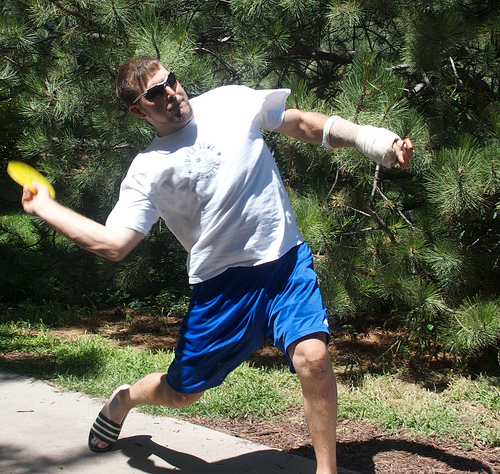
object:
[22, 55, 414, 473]
man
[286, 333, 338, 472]
bare leg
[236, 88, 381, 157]
arm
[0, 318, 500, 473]
trail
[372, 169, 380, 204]
bark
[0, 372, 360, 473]
path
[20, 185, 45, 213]
right hand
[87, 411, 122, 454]
shoe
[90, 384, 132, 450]
right foot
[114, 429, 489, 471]
shadow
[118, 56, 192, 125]
head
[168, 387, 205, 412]
knee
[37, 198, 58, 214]
wrist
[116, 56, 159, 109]
hair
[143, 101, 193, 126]
moustache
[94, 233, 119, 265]
skin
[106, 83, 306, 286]
shirt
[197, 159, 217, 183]
emblem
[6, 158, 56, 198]
frissbe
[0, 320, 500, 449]
grass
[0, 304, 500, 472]
ground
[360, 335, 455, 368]
shade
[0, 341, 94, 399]
edge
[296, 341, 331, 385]
knee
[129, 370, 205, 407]
leg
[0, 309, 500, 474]
floor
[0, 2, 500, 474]
park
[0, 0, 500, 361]
tree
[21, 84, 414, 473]
man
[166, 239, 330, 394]
short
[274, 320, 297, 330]
part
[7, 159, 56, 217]
cast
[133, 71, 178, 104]
sunglasses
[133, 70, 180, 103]
worn